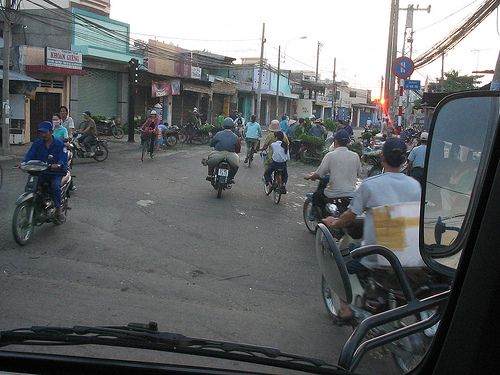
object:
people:
[323, 137, 423, 324]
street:
[0, 97, 437, 375]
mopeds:
[303, 172, 361, 234]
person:
[261, 119, 291, 186]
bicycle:
[261, 149, 282, 204]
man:
[15, 121, 69, 222]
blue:
[28, 141, 69, 197]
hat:
[38, 121, 53, 133]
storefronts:
[25, 46, 84, 143]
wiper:
[0, 315, 348, 375]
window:
[1, 0, 500, 374]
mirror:
[420, 90, 500, 257]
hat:
[268, 119, 282, 131]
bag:
[372, 200, 425, 268]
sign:
[392, 56, 415, 78]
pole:
[397, 78, 404, 138]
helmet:
[222, 118, 234, 128]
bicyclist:
[207, 117, 241, 184]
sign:
[46, 47, 83, 71]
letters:
[51, 51, 80, 61]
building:
[0, 0, 380, 148]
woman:
[138, 110, 159, 159]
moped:
[12, 149, 77, 245]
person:
[263, 131, 290, 189]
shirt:
[347, 171, 423, 271]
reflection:
[425, 97, 491, 254]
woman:
[50, 114, 69, 147]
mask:
[52, 120, 60, 125]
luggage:
[201, 150, 240, 169]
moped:
[206, 159, 236, 197]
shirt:
[140, 116, 160, 135]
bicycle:
[138, 129, 155, 162]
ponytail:
[281, 137, 289, 154]